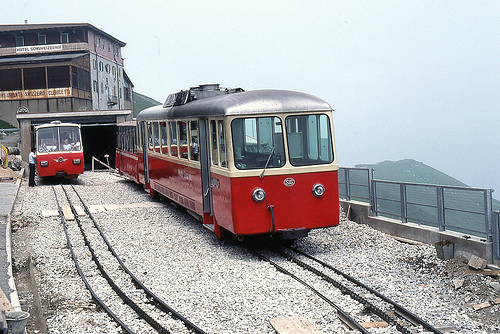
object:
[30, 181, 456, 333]
gravel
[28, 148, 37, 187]
man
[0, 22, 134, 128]
building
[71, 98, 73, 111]
rust stains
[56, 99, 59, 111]
rust stains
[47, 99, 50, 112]
rust stains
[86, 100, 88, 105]
rust stains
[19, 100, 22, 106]
rust stains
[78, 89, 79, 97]
stains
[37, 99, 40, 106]
stains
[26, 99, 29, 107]
stains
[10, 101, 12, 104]
stains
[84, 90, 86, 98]
stains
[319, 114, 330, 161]
window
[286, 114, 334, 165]
window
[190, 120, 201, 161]
window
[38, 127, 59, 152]
window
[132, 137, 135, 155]
window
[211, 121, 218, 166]
window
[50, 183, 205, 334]
track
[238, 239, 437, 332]
track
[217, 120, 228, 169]
window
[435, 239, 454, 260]
trash can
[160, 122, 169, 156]
window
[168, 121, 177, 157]
window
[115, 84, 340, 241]
train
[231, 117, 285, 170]
window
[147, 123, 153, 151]
window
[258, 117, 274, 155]
window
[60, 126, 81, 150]
window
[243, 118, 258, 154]
window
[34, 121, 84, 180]
train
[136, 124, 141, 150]
window